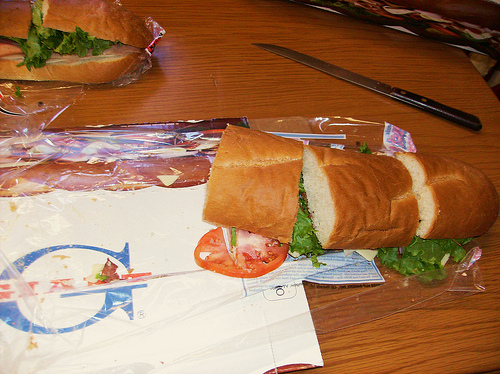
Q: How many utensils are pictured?
A: One.